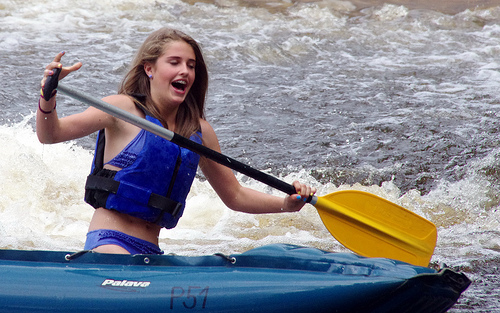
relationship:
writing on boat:
[97, 270, 156, 292] [6, 243, 471, 311]